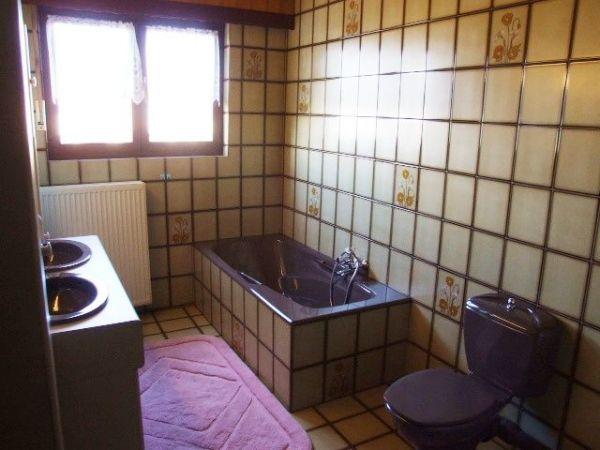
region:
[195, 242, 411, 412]
The bathtub at the corner.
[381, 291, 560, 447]
The purple toilet bowl.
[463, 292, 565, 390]
The purple toilet cistern.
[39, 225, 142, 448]
The double sink on the left.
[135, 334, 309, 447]
A pink carpet in the bathroom.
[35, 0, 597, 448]
The tile finished bathroom.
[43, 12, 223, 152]
The bright window in the background.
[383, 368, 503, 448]
A closed toilet bowl.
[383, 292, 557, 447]
The toilet bowl and cistern system.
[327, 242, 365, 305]
The bathtub water faucet.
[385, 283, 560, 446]
blue toilet in bathroom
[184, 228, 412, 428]
tub in the bathroom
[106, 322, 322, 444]
the rug is purple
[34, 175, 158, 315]
radiator heating on wall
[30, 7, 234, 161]
windows are on wall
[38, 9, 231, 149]
windows have white curtains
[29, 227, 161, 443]
bathroom has a counter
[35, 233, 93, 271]
counter has a sink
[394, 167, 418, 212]
floral pattern on tile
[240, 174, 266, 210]
A tile in a wall.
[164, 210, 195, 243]
A tile in a wall.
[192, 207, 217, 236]
A tile in a wall.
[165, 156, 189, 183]
A tile in a wall.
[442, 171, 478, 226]
tan bathroom tile with brown grout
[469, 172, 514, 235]
tan bathroom tile with brown grout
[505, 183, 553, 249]
tan bathroom tile with brown grout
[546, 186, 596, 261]
tan bathroom tile with brown grout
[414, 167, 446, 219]
tan bathroom tile with brown grout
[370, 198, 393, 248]
tan bathroom tile with brown grout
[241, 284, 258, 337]
tan bathroom tile with brown grout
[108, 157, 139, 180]
tan bathroom tile with brown grout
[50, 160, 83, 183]
tan bathroom tile with brown grout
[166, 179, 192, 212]
tan bathroom tile with brown grout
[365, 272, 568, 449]
Purple toilet in the bathroom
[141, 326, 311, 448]
purple rug on the floor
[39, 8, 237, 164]
window on the wall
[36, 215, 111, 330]
purple sink in the bathroon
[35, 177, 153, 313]
white radiator in the bathroom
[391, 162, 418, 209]
flowers on the tile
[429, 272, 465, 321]
flowers on the tile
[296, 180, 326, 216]
flowers on the tile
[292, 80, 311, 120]
flowers on the tile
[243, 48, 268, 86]
flowers on the tile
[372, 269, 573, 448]
the toilet is purple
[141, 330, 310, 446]
a rug in a toilet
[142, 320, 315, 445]
the rug is purple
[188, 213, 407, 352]
the inside of the bathtub is purple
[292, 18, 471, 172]
light shine on the wall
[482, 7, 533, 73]
flowers on the wall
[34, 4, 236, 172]
sun is shining on the window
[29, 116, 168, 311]
a white heater below the window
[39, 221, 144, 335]
the counter is purple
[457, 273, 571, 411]
the water tank is close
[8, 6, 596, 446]
Outdated bathroom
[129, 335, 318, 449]
Pink fluffy bath rug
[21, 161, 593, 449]
Brown commode, bathtub and sinks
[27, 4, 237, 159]
Sunlight coming from the window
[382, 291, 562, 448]
gray toilet in the bathroom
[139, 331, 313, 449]
pink rug on the floor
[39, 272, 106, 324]
gray bathroom sink on counter